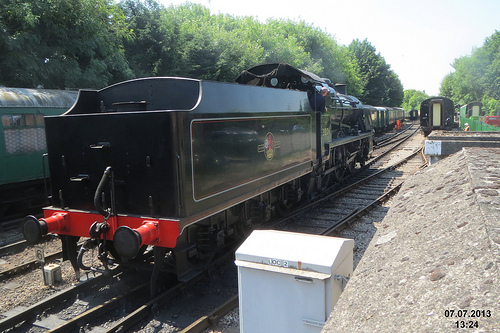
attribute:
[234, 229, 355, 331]
box — white, electrical, control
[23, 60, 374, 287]
train — back, fading, black, car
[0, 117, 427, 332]
track — rusted, small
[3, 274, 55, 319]
stones — round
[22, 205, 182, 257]
bar — red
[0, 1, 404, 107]
tree — line, light, green, side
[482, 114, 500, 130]
truck — red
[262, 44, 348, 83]
smoke — out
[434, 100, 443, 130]
door — white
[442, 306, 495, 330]
numbers — black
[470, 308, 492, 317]
date — 2013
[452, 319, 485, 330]
writing — black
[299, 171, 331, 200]
wheel — black